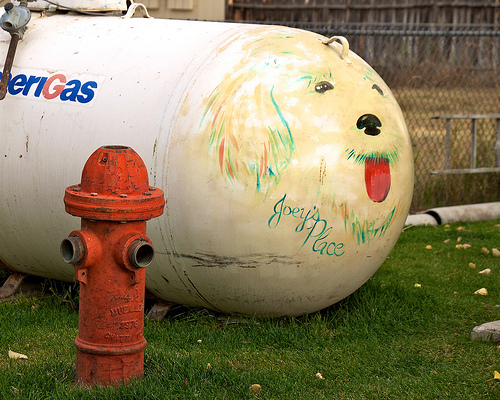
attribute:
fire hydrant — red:
[59, 147, 169, 387]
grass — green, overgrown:
[15, 235, 497, 393]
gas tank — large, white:
[1, 8, 417, 325]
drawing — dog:
[194, 34, 416, 265]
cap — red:
[68, 142, 164, 213]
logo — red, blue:
[6, 61, 101, 103]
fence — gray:
[331, 16, 500, 210]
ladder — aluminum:
[430, 104, 499, 182]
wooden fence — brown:
[314, 2, 499, 119]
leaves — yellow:
[409, 230, 499, 310]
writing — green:
[270, 198, 342, 270]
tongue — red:
[359, 154, 397, 204]